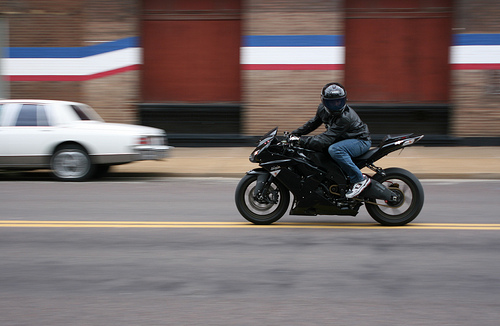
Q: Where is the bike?
A: On the road.